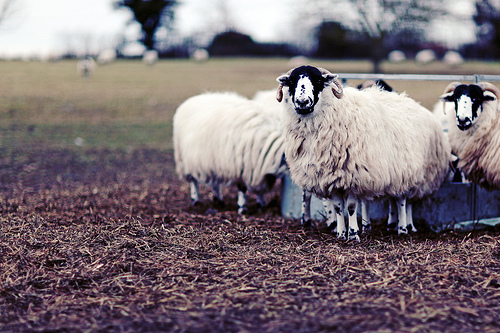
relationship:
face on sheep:
[282, 62, 332, 114] [276, 62, 447, 204]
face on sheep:
[288, 65, 324, 114] [274, 65, 446, 244]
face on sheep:
[288, 65, 324, 114] [131, 14, 481, 256]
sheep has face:
[171, 91, 288, 215] [273, 60, 342, 116]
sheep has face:
[432, 81, 500, 191] [441, 80, 494, 131]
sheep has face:
[274, 65, 446, 244] [288, 65, 324, 114]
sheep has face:
[432, 81, 500, 191] [452, 89, 478, 131]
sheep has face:
[432, 81, 500, 191] [264, 61, 346, 113]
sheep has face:
[432, 81, 500, 191] [442, 85, 490, 130]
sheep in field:
[274, 65, 446, 244] [3, 60, 498, 326]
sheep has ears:
[274, 65, 446, 244] [276, 70, 294, 88]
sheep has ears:
[274, 65, 446, 244] [320, 68, 340, 88]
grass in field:
[3, 121, 172, 150] [0, 58, 500, 160]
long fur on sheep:
[309, 131, 401, 179] [274, 65, 446, 244]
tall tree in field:
[116, 3, 174, 66] [3, 60, 498, 326]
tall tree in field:
[347, 4, 432, 70] [3, 60, 498, 326]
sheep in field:
[154, 45, 471, 266] [19, 61, 404, 293]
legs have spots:
[297, 188, 415, 243] [300, 195, 355, 216]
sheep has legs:
[274, 65, 446, 244] [297, 188, 415, 243]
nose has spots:
[293, 96, 313, 106] [298, 84, 308, 98]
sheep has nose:
[164, 42, 498, 235] [293, 96, 313, 106]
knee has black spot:
[343, 201, 359, 216] [347, 203, 355, 214]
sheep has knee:
[274, 65, 446, 244] [343, 201, 359, 216]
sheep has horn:
[274, 65, 446, 244] [267, 83, 294, 102]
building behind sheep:
[197, 20, 297, 60] [274, 65, 446, 244]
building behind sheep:
[197, 20, 297, 60] [437, 68, 498, 189]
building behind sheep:
[197, 20, 297, 60] [167, 82, 309, 219]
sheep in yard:
[274, 65, 446, 244] [3, 60, 498, 331]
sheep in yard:
[432, 80, 499, 188] [3, 60, 498, 331]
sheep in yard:
[171, 91, 288, 215] [3, 60, 498, 331]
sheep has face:
[432, 81, 500, 191] [454, 84, 484, 131]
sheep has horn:
[274, 65, 446, 244] [320, 70, 350, 106]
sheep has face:
[164, 42, 498, 235] [275, 66, 335, 116]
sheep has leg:
[274, 65, 446, 244] [395, 199, 407, 239]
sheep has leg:
[274, 65, 446, 244] [345, 195, 360, 242]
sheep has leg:
[274, 65, 446, 244] [332, 192, 343, 239]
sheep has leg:
[274, 65, 446, 244] [298, 188, 311, 222]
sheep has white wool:
[274, 65, 446, 244] [340, 103, 440, 189]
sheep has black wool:
[274, 65, 446, 244] [291, 67, 323, 79]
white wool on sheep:
[340, 103, 440, 189] [274, 65, 446, 244]